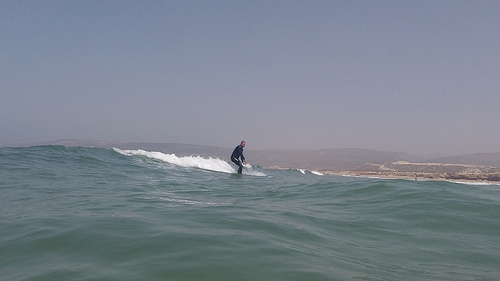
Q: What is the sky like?
A: No clouds.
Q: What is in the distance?
A: Mountain tops.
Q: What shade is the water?
A: Blue green.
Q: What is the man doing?
A: Surfing.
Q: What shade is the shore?
A: Brown.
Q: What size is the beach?
A: Long.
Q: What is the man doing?
A: Surfing.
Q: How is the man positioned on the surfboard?
A: Upright.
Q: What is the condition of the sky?
A: Clear.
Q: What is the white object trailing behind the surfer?
A: The splash of the water.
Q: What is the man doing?
A: Surfing.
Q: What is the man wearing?
A: Wetsuit.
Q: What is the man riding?
A: A wave.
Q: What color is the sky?
A: Blue.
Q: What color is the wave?
A: White.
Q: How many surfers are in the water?
A: One.